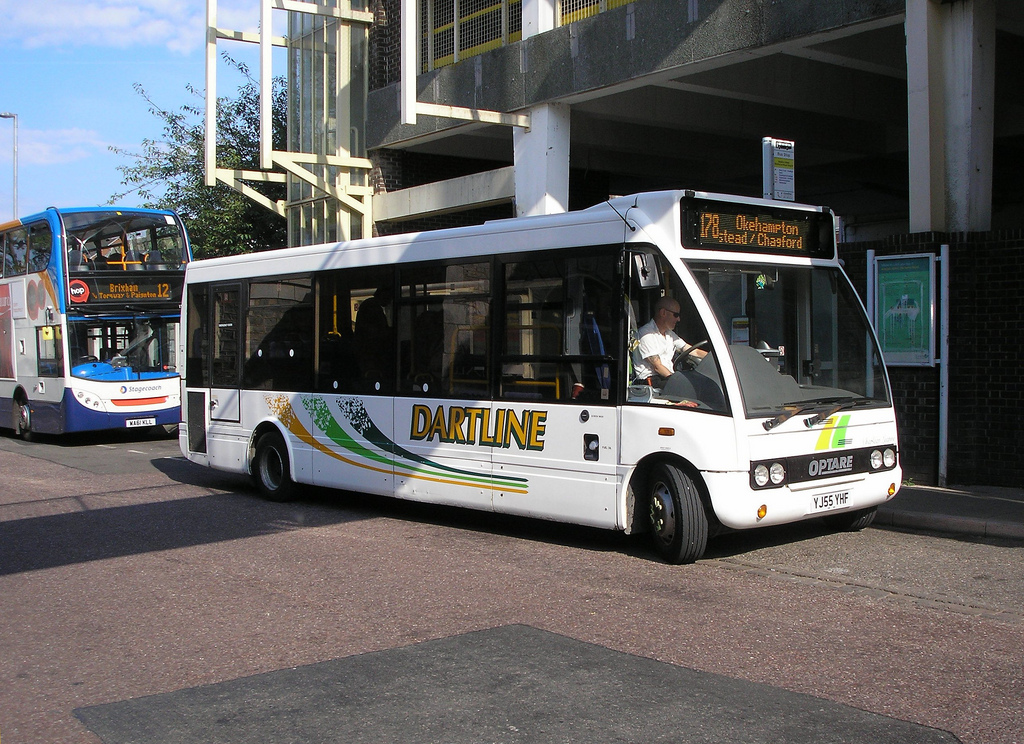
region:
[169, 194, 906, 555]
A white bus stopped at curb.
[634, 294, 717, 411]
Bus driver is wearing a white shirt.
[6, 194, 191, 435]
A blue and white double level bus.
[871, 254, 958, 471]
Green sign on poles.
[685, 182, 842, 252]
Destination written in digital lights.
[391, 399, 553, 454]
Dartline written in gold on bus.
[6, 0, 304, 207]
White clouds in blue sky.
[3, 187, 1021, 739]
Street with buses parked at curb.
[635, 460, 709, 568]
Black front tire on white bus.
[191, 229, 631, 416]
Tinted windows on the bus.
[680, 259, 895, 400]
glass window on bus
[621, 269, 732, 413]
glass window on bus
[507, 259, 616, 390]
glass window on bus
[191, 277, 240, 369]
glass window on bus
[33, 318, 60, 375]
glass window on bus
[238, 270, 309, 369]
glass window on bus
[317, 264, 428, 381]
glass window on bus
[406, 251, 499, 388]
glass window on bus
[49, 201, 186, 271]
glass window on bus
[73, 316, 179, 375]
glass window on bus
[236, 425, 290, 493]
the rear wheel of the bus in front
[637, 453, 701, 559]
the front wheel of the bus in front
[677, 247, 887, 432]
the windshield of the bus in front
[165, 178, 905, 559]
the bus in front is white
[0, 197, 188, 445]
the bus behind the white bus is blue and white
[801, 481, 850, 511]
the front license plate of the white bus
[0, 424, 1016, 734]
the street is grey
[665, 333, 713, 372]
the steering wheel of the white bus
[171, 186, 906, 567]
White big bus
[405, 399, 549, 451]
Dartline sign on the bus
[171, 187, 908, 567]
Driver inside the bus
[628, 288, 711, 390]
Bus driver wearing sunglasses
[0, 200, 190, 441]
Blue double decker bus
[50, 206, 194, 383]
Windshield of the double decker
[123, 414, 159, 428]
Black and white licence plate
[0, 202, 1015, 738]
Buses on the side of the road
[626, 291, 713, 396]
Driver in front of the steering wheel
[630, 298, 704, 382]
man in white shirt drives large white bus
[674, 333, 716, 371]
gray steering wheel in big bus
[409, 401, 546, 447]
yellow Dartline logo on passenger bus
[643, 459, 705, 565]
black front tire on parked bus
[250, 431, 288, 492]
black rear tire on parked bus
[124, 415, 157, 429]
white front license plate on double decker bus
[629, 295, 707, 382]
man wearing black sunglasses steers bus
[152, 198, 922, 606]
white city bus on road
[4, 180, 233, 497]
white and blue bus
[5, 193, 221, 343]
second story on bus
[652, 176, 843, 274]
orange sign on bus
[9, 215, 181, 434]
a tall blue bus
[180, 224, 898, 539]
a large white bus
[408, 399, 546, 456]
writing on the bus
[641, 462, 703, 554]
a tire on the bus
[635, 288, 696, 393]
a man driving the bus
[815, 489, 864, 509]
the license plate on the bus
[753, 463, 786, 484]
headlights on the bus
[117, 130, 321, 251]
a tree next to the bus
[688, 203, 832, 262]
a sign on the bus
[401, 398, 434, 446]
letter on a bus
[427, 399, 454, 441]
letter on a bus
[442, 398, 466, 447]
letter on a bus